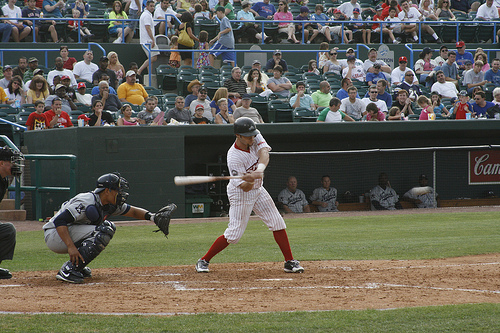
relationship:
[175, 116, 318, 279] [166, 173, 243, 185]
batter ready to swing bat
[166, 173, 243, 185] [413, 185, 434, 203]
bat at ball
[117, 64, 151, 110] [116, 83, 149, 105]
man in shirt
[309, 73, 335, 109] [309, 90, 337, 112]
man in shirt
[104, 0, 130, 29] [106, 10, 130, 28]
person in shirt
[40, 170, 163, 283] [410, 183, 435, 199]
man to catch ball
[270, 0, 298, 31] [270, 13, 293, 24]
woman in blouse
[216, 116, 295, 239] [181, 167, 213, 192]
man swinging baseball bat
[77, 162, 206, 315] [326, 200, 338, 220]
catcher crouched to catch ball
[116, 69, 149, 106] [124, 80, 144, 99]
man in shirt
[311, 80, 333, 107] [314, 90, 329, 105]
man in shirt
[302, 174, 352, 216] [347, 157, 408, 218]
players watching in dugout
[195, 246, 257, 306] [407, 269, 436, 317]
batters box drawn on field